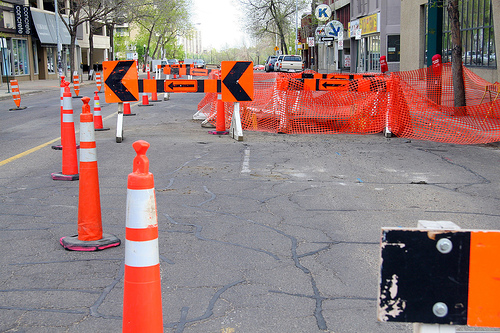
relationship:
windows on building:
[434, 4, 496, 68] [398, 2, 498, 82]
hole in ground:
[403, 173, 433, 190] [391, 144, 428, 196]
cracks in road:
[141, 145, 329, 324] [20, 80, 483, 299]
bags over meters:
[372, 51, 443, 70] [374, 53, 448, 108]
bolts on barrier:
[426, 223, 476, 311] [365, 220, 476, 301]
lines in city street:
[245, 189, 356, 331] [0, 61, 499, 333]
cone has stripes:
[118, 136, 187, 330] [122, 182, 162, 266]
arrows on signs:
[38, 29, 365, 138] [100, 53, 386, 110]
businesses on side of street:
[279, 3, 496, 123] [8, 42, 369, 328]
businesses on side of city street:
[9, 8, 176, 110] [0, 61, 499, 333]